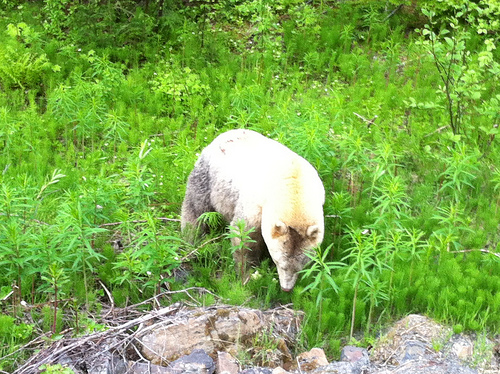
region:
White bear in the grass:
[133, 113, 358, 290]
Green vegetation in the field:
[29, 94, 151, 280]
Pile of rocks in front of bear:
[115, 305, 330, 371]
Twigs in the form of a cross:
[23, 268, 84, 333]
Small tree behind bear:
[423, 32, 487, 136]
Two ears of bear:
[271, 220, 324, 240]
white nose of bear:
[266, 273, 308, 293]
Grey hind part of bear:
[169, 162, 242, 209]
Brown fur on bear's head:
[284, 221, 306, 254]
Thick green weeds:
[401, 238, 488, 313]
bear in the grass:
[187, 106, 354, 323]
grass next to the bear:
[348, 177, 418, 260]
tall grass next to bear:
[368, 170, 428, 226]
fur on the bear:
[250, 142, 310, 195]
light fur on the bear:
[230, 150, 320, 220]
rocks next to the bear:
[196, 310, 251, 346]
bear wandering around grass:
[193, 148, 334, 289]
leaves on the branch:
[422, 22, 477, 95]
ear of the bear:
[298, 220, 326, 252]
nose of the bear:
[261, 268, 309, 306]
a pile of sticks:
[0, 290, 179, 371]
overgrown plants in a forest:
[7, 8, 499, 110]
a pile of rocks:
[142, 303, 494, 372]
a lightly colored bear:
[177, 120, 329, 296]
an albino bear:
[181, 128, 328, 298]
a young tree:
[412, 12, 497, 173]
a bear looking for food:
[157, 121, 347, 305]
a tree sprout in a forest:
[416, 8, 498, 197]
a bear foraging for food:
[185, 123, 337, 308]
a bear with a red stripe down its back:
[175, 132, 336, 302]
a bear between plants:
[167, 108, 363, 291]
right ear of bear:
[269, 223, 285, 237]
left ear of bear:
[300, 218, 322, 238]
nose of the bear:
[280, 284, 294, 296]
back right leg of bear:
[173, 154, 206, 242]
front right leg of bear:
[223, 209, 260, 284]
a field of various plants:
[15, 59, 142, 289]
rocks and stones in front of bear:
[147, 294, 326, 372]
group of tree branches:
[27, 298, 157, 355]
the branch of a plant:
[421, 24, 463, 136]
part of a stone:
[176, 309, 202, 343]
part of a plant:
[329, 299, 347, 329]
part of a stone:
[192, 319, 215, 340]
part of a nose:
[275, 275, 294, 310]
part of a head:
[277, 233, 299, 299]